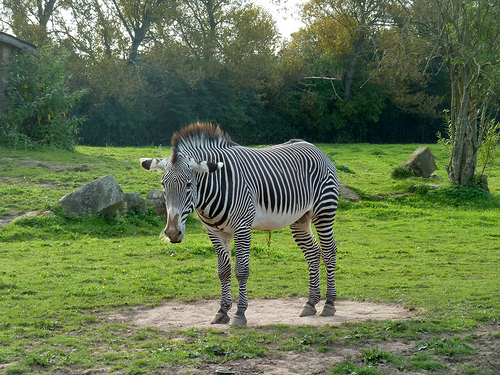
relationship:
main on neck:
[167, 124, 245, 161] [176, 139, 221, 219]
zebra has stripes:
[146, 120, 362, 329] [251, 148, 302, 211]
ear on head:
[138, 155, 165, 173] [142, 151, 224, 256]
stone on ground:
[57, 175, 136, 231] [0, 141, 497, 374]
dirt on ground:
[139, 284, 418, 336] [0, 141, 497, 374]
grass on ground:
[38, 235, 178, 302] [0, 141, 497, 374]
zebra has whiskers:
[146, 120, 362, 329] [155, 231, 170, 248]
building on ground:
[2, 27, 43, 153] [0, 141, 497, 374]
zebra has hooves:
[146, 120, 362, 329] [212, 308, 249, 334]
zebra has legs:
[146, 120, 362, 329] [209, 231, 253, 316]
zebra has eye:
[146, 120, 362, 329] [187, 181, 191, 191]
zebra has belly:
[146, 120, 362, 329] [256, 212, 312, 233]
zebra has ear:
[146, 120, 362, 329] [138, 155, 165, 173]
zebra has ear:
[146, 120, 362, 329] [189, 156, 226, 175]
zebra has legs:
[146, 120, 362, 329] [288, 197, 344, 321]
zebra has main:
[146, 120, 362, 329] [167, 124, 245, 161]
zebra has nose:
[146, 120, 362, 329] [161, 222, 191, 247]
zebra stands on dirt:
[146, 120, 362, 329] [139, 284, 418, 336]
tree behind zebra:
[179, 3, 240, 132] [146, 120, 362, 329]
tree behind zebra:
[100, 2, 190, 140] [146, 120, 362, 329]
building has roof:
[2, 27, 43, 153] [1, 29, 39, 57]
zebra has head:
[146, 120, 362, 329] [142, 151, 224, 256]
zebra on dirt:
[146, 120, 362, 329] [139, 284, 418, 336]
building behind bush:
[2, 27, 43, 153] [11, 56, 74, 156]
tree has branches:
[179, 3, 240, 132] [218, 18, 245, 39]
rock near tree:
[402, 143, 439, 184] [421, 7, 498, 207]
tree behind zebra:
[421, 7, 498, 207] [146, 120, 362, 329]